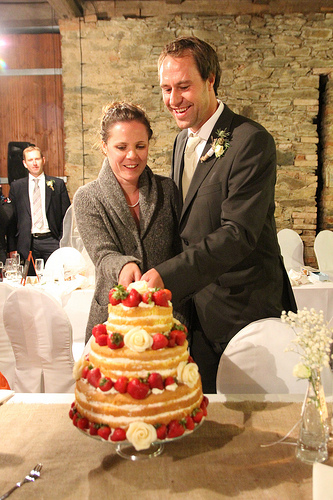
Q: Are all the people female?
A: No, they are both male and female.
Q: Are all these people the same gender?
A: No, they are both male and female.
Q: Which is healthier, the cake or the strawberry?
A: The strawberry is healthier than the cake.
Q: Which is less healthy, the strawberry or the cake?
A: The cake is less healthy than the strawberry.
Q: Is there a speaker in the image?
A: Yes, there is a speaker.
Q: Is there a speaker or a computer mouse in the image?
A: Yes, there is a speaker.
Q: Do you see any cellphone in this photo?
A: No, there are no cell phones.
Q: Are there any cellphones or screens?
A: No, there are no cellphones or screens.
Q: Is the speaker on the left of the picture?
A: Yes, the speaker is on the left of the image.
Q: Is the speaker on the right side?
A: No, the speaker is on the left of the image.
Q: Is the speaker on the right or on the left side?
A: The speaker is on the left of the image.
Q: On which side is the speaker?
A: The speaker is on the left of the image.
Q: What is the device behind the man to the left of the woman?
A: The device is a speaker.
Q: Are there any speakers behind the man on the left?
A: Yes, there is a speaker behind the man.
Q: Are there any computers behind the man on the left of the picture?
A: No, there is a speaker behind the man.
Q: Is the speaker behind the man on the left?
A: Yes, the speaker is behind the man.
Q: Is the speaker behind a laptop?
A: No, the speaker is behind the man.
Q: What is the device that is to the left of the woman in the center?
A: The device is a speaker.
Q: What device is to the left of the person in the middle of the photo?
A: The device is a speaker.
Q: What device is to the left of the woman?
A: The device is a speaker.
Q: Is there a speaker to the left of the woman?
A: Yes, there is a speaker to the left of the woman.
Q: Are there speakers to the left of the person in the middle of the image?
A: Yes, there is a speaker to the left of the woman.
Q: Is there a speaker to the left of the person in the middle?
A: Yes, there is a speaker to the left of the woman.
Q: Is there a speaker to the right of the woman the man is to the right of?
A: No, the speaker is to the left of the woman.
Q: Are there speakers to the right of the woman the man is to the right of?
A: No, the speaker is to the left of the woman.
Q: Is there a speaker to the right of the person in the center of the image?
A: No, the speaker is to the left of the woman.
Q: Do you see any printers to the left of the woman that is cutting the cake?
A: No, there is a speaker to the left of the woman.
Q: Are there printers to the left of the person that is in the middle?
A: No, there is a speaker to the left of the woman.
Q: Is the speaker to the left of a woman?
A: Yes, the speaker is to the left of a woman.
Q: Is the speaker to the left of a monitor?
A: No, the speaker is to the left of a woman.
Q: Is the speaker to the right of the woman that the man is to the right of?
A: No, the speaker is to the left of the woman.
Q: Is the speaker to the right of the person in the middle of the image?
A: No, the speaker is to the left of the woman.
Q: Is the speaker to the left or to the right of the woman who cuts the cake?
A: The speaker is to the left of the woman.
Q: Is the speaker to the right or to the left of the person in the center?
A: The speaker is to the left of the woman.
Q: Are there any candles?
A: No, there are no candles.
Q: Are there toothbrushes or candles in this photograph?
A: No, there are no candles or toothbrushes.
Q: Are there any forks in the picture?
A: Yes, there is a fork.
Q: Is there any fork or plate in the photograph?
A: Yes, there is a fork.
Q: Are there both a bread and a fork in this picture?
A: No, there is a fork but no breads.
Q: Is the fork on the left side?
A: Yes, the fork is on the left of the image.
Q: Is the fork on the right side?
A: No, the fork is on the left of the image.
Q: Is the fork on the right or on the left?
A: The fork is on the left of the image.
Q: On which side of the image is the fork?
A: The fork is on the left of the image.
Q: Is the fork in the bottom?
A: Yes, the fork is in the bottom of the image.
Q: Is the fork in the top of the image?
A: No, the fork is in the bottom of the image.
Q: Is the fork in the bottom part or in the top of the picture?
A: The fork is in the bottom of the image.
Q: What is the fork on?
A: The fork is on the table.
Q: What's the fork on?
A: The fork is on the table.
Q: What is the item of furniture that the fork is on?
A: The piece of furniture is a table.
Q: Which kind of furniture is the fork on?
A: The fork is on the table.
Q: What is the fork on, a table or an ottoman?
A: The fork is on a table.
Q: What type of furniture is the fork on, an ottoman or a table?
A: The fork is on a table.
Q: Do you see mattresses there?
A: No, there are no mattresses.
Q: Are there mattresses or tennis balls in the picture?
A: No, there are no mattresses or tennis balls.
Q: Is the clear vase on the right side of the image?
A: Yes, the vase is on the right of the image.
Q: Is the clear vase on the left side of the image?
A: No, the vase is on the right of the image.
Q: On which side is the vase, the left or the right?
A: The vase is on the right of the image.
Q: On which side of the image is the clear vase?
A: The vase is on the right of the image.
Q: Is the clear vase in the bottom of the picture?
A: Yes, the vase is in the bottom of the image.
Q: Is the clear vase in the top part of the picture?
A: No, the vase is in the bottom of the image.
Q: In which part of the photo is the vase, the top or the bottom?
A: The vase is in the bottom of the image.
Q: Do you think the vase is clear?
A: Yes, the vase is clear.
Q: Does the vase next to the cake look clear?
A: Yes, the vase is clear.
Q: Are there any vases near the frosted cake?
A: Yes, there is a vase near the cake.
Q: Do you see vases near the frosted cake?
A: Yes, there is a vase near the cake.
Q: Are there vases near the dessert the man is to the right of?
A: Yes, there is a vase near the cake.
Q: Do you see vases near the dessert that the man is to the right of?
A: Yes, there is a vase near the cake.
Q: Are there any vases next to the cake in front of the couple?
A: Yes, there is a vase next to the cake.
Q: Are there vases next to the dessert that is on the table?
A: Yes, there is a vase next to the cake.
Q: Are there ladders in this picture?
A: No, there are no ladders.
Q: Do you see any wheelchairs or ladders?
A: No, there are no ladders or wheelchairs.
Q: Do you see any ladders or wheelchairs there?
A: No, there are no ladders or wheelchairs.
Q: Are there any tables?
A: Yes, there is a table.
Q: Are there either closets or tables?
A: Yes, there is a table.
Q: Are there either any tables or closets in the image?
A: Yes, there is a table.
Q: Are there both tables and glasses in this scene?
A: Yes, there are both a table and glasses.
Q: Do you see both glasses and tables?
A: Yes, there are both a table and glasses.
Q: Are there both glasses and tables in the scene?
A: Yes, there are both a table and glasses.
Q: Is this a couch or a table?
A: This is a table.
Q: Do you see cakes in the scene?
A: Yes, there is a cake.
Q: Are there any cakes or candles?
A: Yes, there is a cake.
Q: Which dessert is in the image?
A: The dessert is a cake.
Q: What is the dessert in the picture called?
A: The dessert is a cake.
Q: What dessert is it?
A: The dessert is a cake.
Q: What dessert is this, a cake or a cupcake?
A: That is a cake.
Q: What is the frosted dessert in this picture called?
A: The dessert is a cake.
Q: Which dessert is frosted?
A: The dessert is a cake.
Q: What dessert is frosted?
A: The dessert is a cake.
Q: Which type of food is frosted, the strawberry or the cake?
A: The cake is frosted.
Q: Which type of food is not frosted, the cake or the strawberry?
A: The strawberry is not frosted.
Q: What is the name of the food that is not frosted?
A: The food is a strawberry.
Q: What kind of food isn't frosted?
A: The food is a strawberry.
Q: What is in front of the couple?
A: The cake is in front of the couple.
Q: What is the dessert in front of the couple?
A: The dessert is a cake.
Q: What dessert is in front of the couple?
A: The dessert is a cake.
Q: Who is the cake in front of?
A: The cake is in front of the couple.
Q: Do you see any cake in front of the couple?
A: Yes, there is a cake in front of the couple.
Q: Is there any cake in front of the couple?
A: Yes, there is a cake in front of the couple.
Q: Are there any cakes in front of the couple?
A: Yes, there is a cake in front of the couple.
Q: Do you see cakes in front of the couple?
A: Yes, there is a cake in front of the couple.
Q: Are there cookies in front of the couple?
A: No, there is a cake in front of the couple.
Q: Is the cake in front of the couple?
A: Yes, the cake is in front of the couple.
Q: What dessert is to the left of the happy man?
A: The dessert is a cake.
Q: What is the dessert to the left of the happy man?
A: The dessert is a cake.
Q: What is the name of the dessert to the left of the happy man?
A: The dessert is a cake.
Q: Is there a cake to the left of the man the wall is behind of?
A: Yes, there is a cake to the left of the man.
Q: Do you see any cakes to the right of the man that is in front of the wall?
A: No, the cake is to the left of the man.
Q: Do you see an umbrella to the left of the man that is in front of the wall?
A: No, there is a cake to the left of the man.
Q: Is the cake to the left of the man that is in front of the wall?
A: Yes, the cake is to the left of the man.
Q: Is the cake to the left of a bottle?
A: No, the cake is to the left of the man.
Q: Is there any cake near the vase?
A: Yes, there is a cake near the vase.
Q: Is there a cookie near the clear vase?
A: No, there is a cake near the vase.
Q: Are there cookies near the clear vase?
A: No, there is a cake near the vase.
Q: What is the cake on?
A: The cake is on the table.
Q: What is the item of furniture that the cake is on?
A: The piece of furniture is a table.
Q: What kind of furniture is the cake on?
A: The cake is on the table.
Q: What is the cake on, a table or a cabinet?
A: The cake is on a table.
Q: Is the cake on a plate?
A: No, the cake is on a table.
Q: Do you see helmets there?
A: No, there are no helmets.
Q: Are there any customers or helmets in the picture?
A: No, there are no helmets or customers.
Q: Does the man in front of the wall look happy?
A: Yes, the man is happy.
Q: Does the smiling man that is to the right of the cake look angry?
A: No, the man is happy.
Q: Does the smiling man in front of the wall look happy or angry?
A: The man is happy.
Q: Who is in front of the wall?
A: The man is in front of the wall.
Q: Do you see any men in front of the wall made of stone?
A: Yes, there is a man in front of the wall.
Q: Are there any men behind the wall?
A: No, the man is in front of the wall.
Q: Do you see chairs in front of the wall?
A: No, there is a man in front of the wall.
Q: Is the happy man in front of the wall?
A: Yes, the man is in front of the wall.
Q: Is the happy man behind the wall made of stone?
A: No, the man is in front of the wall.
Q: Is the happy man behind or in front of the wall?
A: The man is in front of the wall.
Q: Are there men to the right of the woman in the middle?
A: Yes, there is a man to the right of the woman.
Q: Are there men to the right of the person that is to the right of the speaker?
A: Yes, there is a man to the right of the woman.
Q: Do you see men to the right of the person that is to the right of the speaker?
A: Yes, there is a man to the right of the woman.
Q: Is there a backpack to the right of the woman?
A: No, there is a man to the right of the woman.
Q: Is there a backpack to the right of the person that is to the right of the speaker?
A: No, there is a man to the right of the woman.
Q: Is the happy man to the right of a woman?
A: Yes, the man is to the right of a woman.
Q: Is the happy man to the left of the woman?
A: No, the man is to the right of the woman.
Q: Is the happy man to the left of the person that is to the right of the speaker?
A: No, the man is to the right of the woman.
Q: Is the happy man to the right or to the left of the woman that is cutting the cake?
A: The man is to the right of the woman.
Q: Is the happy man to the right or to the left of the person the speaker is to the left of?
A: The man is to the right of the woman.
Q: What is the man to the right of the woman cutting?
A: The man is cutting the cake.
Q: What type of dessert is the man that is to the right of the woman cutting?
A: The man is cutting the cake.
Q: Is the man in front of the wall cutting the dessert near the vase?
A: Yes, the man is cutting the cake.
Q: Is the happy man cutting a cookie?
A: No, the man is cutting the cake.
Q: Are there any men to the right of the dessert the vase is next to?
A: Yes, there is a man to the right of the cake.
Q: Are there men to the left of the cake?
A: No, the man is to the right of the cake.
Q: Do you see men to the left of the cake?
A: No, the man is to the right of the cake.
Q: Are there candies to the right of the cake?
A: No, there is a man to the right of the cake.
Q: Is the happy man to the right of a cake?
A: Yes, the man is to the right of a cake.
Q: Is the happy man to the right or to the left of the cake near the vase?
A: The man is to the right of the cake.